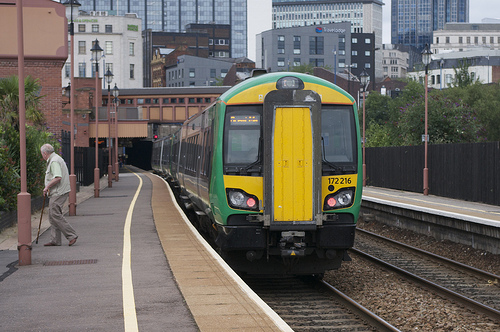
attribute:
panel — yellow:
[269, 100, 316, 219]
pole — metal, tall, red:
[67, 4, 77, 222]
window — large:
[293, 107, 397, 195]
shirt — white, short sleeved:
[42, 155, 72, 197]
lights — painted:
[11, 63, 171, 227]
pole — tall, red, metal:
[15, 15, 27, 270]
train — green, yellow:
[148, 68, 363, 288]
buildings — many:
[87, 23, 415, 83]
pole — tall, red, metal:
[354, 87, 373, 187]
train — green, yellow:
[143, 65, 372, 274]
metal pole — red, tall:
[112, 103, 119, 183]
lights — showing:
[231, 113, 260, 125]